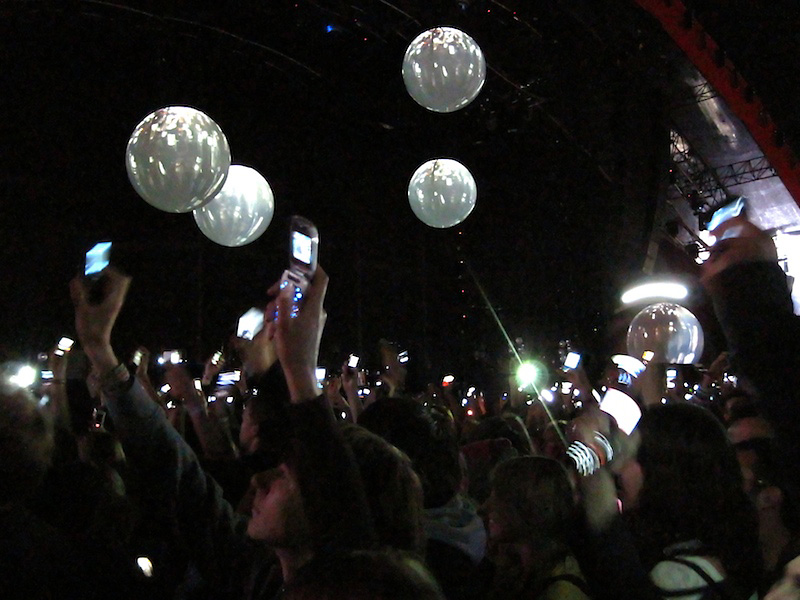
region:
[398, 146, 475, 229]
silver ball in the sky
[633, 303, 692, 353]
silver ball in the sky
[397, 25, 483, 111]
silver ball in the sky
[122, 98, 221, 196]
silver ball in the sky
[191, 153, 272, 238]
silver ball in the sky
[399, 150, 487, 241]
silver ball in the sky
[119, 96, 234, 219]
silver ball in the sky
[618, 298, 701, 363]
silver ball in the sky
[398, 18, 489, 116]
silver ball in the sky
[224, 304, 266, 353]
person holding a cellphone in the sky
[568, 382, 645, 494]
person holding a cellphone in the sky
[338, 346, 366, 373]
person holding a cellphone in the sky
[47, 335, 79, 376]
person holding a cellphone in the sky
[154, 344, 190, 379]
person holding a cellphone in the sky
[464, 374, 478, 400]
person holding a cellphone in the sky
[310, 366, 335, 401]
person holding a cellphone in the sky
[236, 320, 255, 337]
light of the phone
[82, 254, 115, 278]
light of the phone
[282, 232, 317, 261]
light of the phone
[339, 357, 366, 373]
light of the phone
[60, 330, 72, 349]
light of the phone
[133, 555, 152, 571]
light of the phone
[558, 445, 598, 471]
light of the phone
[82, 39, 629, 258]
Orbs in the sky.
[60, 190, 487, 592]
People holding phones.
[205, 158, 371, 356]
Cell phone in woman's hand.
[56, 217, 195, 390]
Cell phone with screen lit up.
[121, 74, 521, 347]
White globe in the sky.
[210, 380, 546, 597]
Woman in the foreground.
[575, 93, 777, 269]
Building in the background.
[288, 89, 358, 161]
a view of dark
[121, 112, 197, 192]
a view of plats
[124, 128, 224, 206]
a view of balls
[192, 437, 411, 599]
a view of man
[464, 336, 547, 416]
a view of light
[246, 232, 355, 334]
a view of mobile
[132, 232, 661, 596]
a group of people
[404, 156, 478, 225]
A ball hanging down.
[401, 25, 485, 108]
A ball hanging down.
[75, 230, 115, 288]
cell phone being held in the air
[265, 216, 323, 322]
cell phone being held in the air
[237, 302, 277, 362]
cell phone being held in the air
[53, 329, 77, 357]
cell phone being held in the air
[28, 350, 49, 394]
cell phone being held in the air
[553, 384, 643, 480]
cell phone being held in the air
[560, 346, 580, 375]
cell phone being held in the air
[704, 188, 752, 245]
cell phone being held in the air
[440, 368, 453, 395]
cell phone being held in the air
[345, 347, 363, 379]
cell phone being held in the air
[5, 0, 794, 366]
The sky is very dark.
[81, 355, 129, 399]
The woman is wearing a watch.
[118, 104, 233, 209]
The ball in the forefront is white in color.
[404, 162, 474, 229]
The ball in the background is white in color.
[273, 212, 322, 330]
The cell phone is silver in color.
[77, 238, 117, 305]
The cell phone is black in color.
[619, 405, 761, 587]
The woman has black hair.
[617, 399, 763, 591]
The woman has long hair.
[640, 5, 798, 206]
The object on the right is red in color.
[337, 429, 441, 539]
the hair of a man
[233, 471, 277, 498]
the nose of a man